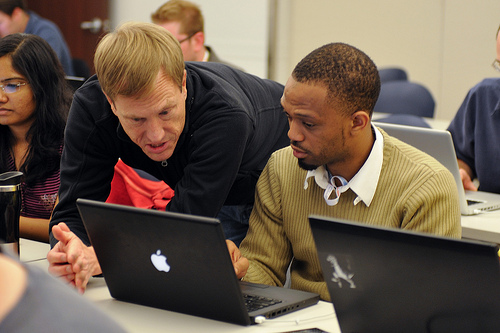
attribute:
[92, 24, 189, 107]
hair — brown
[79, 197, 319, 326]
laptop — apple, black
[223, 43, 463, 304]
man — bent, looking, leaning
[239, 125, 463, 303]
shirt — brown, black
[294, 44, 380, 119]
hair — black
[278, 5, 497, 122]
wall — white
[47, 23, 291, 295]
man — light skinned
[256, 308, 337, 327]
cable — white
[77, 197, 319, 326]
computer — apple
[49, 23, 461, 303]
men — looking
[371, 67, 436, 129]
chair — blue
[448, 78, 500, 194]
shirt — blue